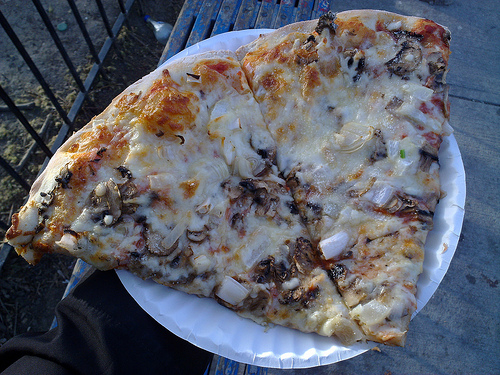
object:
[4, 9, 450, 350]
pizza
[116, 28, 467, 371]
plate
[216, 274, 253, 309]
onion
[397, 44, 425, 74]
olive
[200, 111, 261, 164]
cheese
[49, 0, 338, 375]
bench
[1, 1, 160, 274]
railing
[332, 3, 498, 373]
floor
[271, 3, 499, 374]
sidewalk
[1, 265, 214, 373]
arm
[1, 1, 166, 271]
fence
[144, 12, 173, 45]
bottle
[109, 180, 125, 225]
mushroom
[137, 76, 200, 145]
bubble